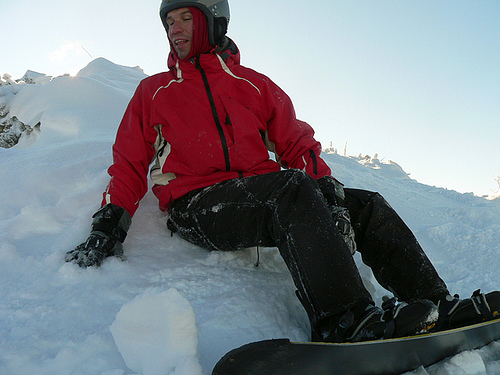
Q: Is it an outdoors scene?
A: Yes, it is outdoors.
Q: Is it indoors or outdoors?
A: It is outdoors.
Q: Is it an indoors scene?
A: No, it is outdoors.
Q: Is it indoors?
A: No, it is outdoors.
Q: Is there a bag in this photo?
A: No, there are no bags.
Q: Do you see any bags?
A: No, there are no bags.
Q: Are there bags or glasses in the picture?
A: No, there are no bags or glasses.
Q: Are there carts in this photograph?
A: No, there are no carts.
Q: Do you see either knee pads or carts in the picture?
A: No, there are no carts or knee pads.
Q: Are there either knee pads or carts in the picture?
A: No, there are no carts or knee pads.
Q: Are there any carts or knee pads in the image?
A: No, there are no carts or knee pads.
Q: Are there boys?
A: No, there are no boys.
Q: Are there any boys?
A: No, there are no boys.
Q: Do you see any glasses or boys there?
A: No, there are no boys or glasses.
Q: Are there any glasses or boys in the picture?
A: No, there are no boys or glasses.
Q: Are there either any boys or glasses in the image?
A: No, there are no boys or glasses.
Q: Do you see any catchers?
A: No, there are no catchers.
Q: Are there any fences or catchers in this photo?
A: No, there are no catchers or fences.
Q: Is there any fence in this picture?
A: No, there are no fences.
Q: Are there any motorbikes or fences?
A: No, there are no fences or motorbikes.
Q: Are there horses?
A: No, there are no horses.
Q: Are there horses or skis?
A: No, there are no horses or skis.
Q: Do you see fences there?
A: No, there are no fences.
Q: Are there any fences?
A: No, there are no fences.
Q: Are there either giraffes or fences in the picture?
A: No, there are no fences or giraffes.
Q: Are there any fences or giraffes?
A: No, there are no fences or giraffes.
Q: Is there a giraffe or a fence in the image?
A: No, there are no fences or giraffes.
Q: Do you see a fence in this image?
A: No, there are no fences.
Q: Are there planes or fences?
A: No, there are no fences or planes.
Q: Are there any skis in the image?
A: No, there are no skis.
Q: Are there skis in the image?
A: No, there are no skis.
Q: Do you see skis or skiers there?
A: No, there are no skis or skiers.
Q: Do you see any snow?
A: Yes, there is snow.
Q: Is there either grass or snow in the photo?
A: Yes, there is snow.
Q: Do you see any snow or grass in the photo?
A: Yes, there is snow.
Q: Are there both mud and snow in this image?
A: No, there is snow but no mud.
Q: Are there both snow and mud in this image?
A: No, there is snow but no mud.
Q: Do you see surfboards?
A: No, there are no surfboards.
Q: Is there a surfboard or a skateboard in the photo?
A: No, there are no surfboards or skateboards.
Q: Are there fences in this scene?
A: No, there are no fences.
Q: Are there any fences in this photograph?
A: No, there are no fences.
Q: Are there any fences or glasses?
A: No, there are no fences or glasses.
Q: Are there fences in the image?
A: No, there are no fences.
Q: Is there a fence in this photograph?
A: No, there are no fences.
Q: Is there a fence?
A: No, there are no fences.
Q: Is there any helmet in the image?
A: Yes, there is a helmet.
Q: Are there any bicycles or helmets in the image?
A: Yes, there is a helmet.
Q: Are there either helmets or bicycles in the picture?
A: Yes, there is a helmet.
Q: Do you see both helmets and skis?
A: No, there is a helmet but no skis.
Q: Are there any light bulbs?
A: No, there are no light bulbs.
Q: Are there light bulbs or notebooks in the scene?
A: No, there are no light bulbs or notebooks.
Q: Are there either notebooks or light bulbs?
A: No, there are no light bulbs or notebooks.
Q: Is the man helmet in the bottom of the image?
A: No, the helmet is in the top of the image.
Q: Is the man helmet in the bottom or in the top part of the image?
A: The helmet is in the top of the image.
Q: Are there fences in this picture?
A: No, there are no fences.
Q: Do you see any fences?
A: No, there are no fences.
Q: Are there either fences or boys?
A: No, there are no fences or boys.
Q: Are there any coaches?
A: No, there are no coaches.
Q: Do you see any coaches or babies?
A: No, there are no coaches or babies.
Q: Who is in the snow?
A: The man is in the snow.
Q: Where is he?
A: The man is in the snow.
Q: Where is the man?
A: The man is in the snow.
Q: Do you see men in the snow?
A: Yes, there is a man in the snow.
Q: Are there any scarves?
A: Yes, there is a scarf.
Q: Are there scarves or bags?
A: Yes, there is a scarf.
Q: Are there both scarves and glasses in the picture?
A: No, there is a scarf but no glasses.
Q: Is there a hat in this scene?
A: No, there are no hats.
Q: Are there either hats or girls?
A: No, there are no hats or girls.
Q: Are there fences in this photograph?
A: No, there are no fences.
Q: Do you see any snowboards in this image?
A: Yes, there is a snowboard.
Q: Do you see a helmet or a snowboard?
A: Yes, there is a snowboard.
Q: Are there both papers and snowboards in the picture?
A: No, there is a snowboard but no papers.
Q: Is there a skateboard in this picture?
A: No, there are no skateboards.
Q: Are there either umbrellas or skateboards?
A: No, there are no skateboards or umbrellas.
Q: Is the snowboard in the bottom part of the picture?
A: Yes, the snowboard is in the bottom of the image.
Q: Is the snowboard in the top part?
A: No, the snowboard is in the bottom of the image.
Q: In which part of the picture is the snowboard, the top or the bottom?
A: The snowboard is in the bottom of the image.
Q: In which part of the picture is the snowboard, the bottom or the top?
A: The snowboard is in the bottom of the image.